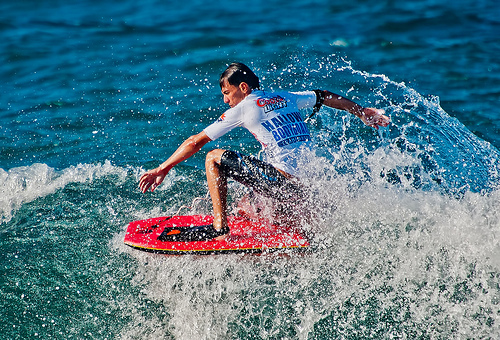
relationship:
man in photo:
[137, 59, 388, 244] [5, 4, 497, 338]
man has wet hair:
[137, 62, 389, 241] [207, 54, 266, 90]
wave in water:
[290, 259, 483, 336] [23, 44, 92, 136]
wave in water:
[290, 259, 483, 336] [0, 0, 498, 338]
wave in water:
[290, 259, 483, 336] [306, 285, 351, 317]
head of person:
[216, 61, 268, 108] [184, 52, 374, 234]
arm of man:
[312, 89, 399, 135] [137, 62, 389, 241]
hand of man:
[130, 167, 178, 198] [137, 62, 389, 241]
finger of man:
[133, 171, 149, 183] [137, 62, 389, 241]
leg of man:
[190, 148, 300, 238] [137, 62, 389, 241]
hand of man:
[361, 109, 391, 131] [137, 62, 389, 241]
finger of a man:
[374, 119, 399, 127] [137, 62, 389, 241]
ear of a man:
[237, 79, 252, 95] [137, 62, 389, 241]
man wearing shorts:
[137, 62, 389, 241] [220, 150, 312, 205]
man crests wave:
[137, 62, 389, 241] [124, 63, 497, 337]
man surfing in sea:
[137, 59, 388, 244] [9, 5, 487, 57]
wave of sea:
[290, 259, 483, 336] [26, 19, 449, 329]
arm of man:
[138, 113, 240, 195] [137, 62, 389, 241]